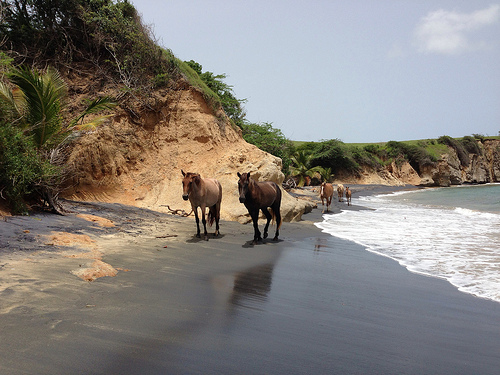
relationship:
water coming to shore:
[316, 184, 498, 308] [312, 186, 425, 375]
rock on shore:
[416, 177, 434, 186] [312, 186, 425, 375]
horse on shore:
[337, 184, 345, 202] [312, 186, 425, 375]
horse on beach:
[233, 173, 282, 246] [1, 184, 500, 375]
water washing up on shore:
[316, 184, 498, 308] [312, 186, 425, 375]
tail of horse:
[206, 206, 217, 230] [179, 170, 222, 242]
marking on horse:
[320, 186, 324, 195] [319, 183, 334, 215]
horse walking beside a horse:
[233, 173, 282, 246] [179, 170, 222, 242]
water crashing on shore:
[316, 184, 498, 308] [312, 186, 425, 375]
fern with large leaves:
[291, 152, 321, 188] [307, 165, 328, 174]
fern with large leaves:
[291, 152, 321, 188] [300, 151, 305, 163]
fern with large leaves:
[291, 152, 321, 188] [305, 169, 316, 180]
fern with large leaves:
[291, 152, 321, 188] [292, 160, 301, 167]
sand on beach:
[53, 231, 118, 280] [1, 184, 500, 375]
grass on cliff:
[170, 56, 219, 103] [6, 29, 305, 225]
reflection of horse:
[232, 263, 273, 300] [233, 173, 282, 246]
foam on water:
[313, 210, 499, 301] [316, 184, 498, 308]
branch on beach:
[167, 206, 192, 218] [1, 184, 500, 375]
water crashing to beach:
[316, 184, 498, 308] [1, 184, 500, 375]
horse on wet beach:
[233, 173, 282, 246] [1, 184, 500, 375]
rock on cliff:
[257, 141, 286, 185] [6, 29, 305, 225]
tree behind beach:
[2, 1, 149, 50] [1, 184, 500, 375]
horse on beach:
[179, 170, 222, 242] [1, 184, 500, 375]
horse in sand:
[179, 170, 222, 242] [53, 231, 118, 280]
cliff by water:
[6, 29, 305, 225] [316, 184, 498, 308]